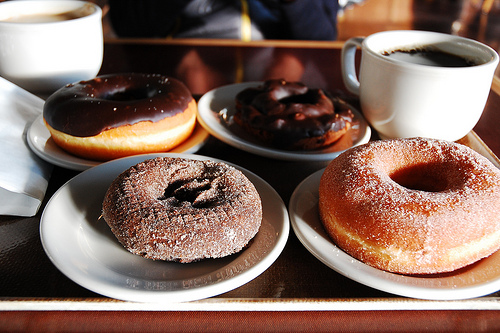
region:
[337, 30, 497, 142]
a white cup on a glass table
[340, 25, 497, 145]
a white cup filled with dark coffee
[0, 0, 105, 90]
a white cup filled with coffee and milk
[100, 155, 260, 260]
a chocolate doughnut with powdered sugar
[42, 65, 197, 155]
a chocolate doughnut on a plate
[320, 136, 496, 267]
a plan doughnut with powdered sugar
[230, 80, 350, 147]
a doughnut with chocolate glaze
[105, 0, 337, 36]
person sitting at a table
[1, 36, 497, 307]
a glass table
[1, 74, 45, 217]
a white paper napkin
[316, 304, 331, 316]
part of a board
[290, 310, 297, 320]
edge of a board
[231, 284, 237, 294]
part of a plate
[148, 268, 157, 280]
edge of a plate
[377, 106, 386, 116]
edge of a cup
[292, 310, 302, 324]
edge of a table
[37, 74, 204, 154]
A chocolate glazed donut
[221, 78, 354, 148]
A chocolate glazed donut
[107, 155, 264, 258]
A powered donut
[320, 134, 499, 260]
A sugar frosted donut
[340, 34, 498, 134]
A cup of coffee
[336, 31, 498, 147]
A white mug of coffee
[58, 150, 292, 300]
A donut on a plate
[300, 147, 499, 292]
A donut on a plate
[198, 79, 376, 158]
A donut on a plate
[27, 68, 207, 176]
A donut on a plate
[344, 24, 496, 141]
a white coffee cup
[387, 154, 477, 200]
the donut has a hole in the middle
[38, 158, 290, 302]
the donut is on a small white dish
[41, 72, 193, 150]
the donut has chocolate frosting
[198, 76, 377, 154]
chocolate frosted pastry on a white dish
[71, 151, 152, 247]
the shadow of the donut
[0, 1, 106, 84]
a white cup in back of the chocolate donut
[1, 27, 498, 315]
pastries and cup of coffee on a tray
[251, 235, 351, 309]
the serving tray is brown with white edge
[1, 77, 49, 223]
a white napkin on the serving tray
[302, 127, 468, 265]
a donut covered with sugar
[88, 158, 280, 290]
a donut covered with sugar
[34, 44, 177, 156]
donut with chocolate frosting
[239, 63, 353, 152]
donut with chocolate frosting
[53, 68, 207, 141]
donut with chocolate frosting